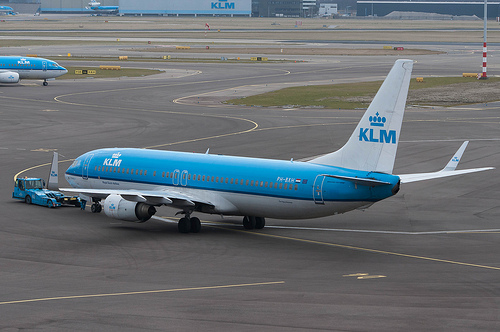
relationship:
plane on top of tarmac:
[44, 74, 414, 248] [9, 221, 496, 327]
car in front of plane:
[11, 178, 84, 208] [38, 96, 426, 247]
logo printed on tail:
[358, 110, 393, 128] [325, 51, 427, 176]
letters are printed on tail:
[351, 122, 402, 149] [324, 58, 435, 196]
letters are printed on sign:
[201, 0, 236, 16] [114, 0, 256, 15]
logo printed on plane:
[100, 148, 120, 158] [30, 74, 416, 229]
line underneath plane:
[260, 224, 499, 297] [47, 82, 444, 242]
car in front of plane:
[14, 163, 59, 206] [28, 60, 448, 230]